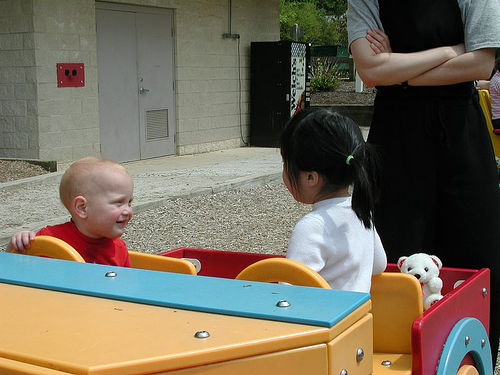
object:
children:
[275, 108, 386, 297]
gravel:
[126, 177, 317, 249]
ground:
[0, 123, 375, 257]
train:
[0, 230, 495, 368]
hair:
[278, 107, 376, 229]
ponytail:
[343, 144, 372, 231]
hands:
[8, 228, 35, 254]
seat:
[6, 234, 87, 265]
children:
[7, 157, 137, 268]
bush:
[303, 57, 345, 92]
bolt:
[195, 330, 209, 339]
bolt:
[277, 300, 289, 308]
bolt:
[105, 271, 116, 277]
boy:
[11, 154, 136, 264]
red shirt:
[34, 218, 130, 268]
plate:
[54, 62, 86, 88]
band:
[345, 155, 354, 165]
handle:
[136, 70, 151, 95]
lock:
[139, 85, 150, 95]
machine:
[242, 37, 314, 150]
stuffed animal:
[396, 252, 443, 306]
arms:
[399, 0, 500, 87]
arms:
[338, 0, 446, 82]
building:
[0, 0, 282, 177]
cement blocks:
[71, 145, 96, 160]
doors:
[92, 3, 181, 162]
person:
[346, 0, 500, 366]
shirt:
[346, 1, 498, 54]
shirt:
[282, 198, 386, 294]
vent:
[144, 107, 169, 141]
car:
[0, 233, 489, 375]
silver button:
[480, 287, 489, 297]